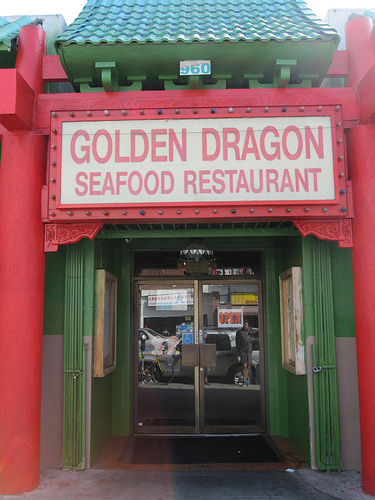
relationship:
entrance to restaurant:
[117, 245, 280, 444] [2, 0, 372, 497]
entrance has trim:
[117, 245, 280, 444] [114, 241, 282, 438]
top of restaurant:
[55, 0, 340, 82] [0, 0, 375, 500]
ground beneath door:
[19, 463, 370, 499] [133, 277, 267, 435]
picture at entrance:
[91, 269, 122, 378] [117, 245, 280, 444]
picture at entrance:
[274, 265, 308, 375] [117, 245, 280, 444]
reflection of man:
[230, 319, 257, 387] [230, 319, 258, 390]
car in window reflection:
[145, 327, 261, 384] [129, 281, 260, 388]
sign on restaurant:
[45, 106, 344, 213] [2, 0, 372, 497]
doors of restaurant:
[132, 277, 266, 436] [2, 0, 372, 497]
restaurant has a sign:
[2, 0, 372, 497] [45, 106, 344, 213]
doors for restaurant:
[132, 277, 266, 436] [2, 0, 372, 497]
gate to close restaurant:
[62, 245, 91, 473] [2, 0, 372, 497]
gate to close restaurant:
[299, 230, 348, 475] [2, 0, 372, 497]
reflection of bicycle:
[137, 338, 179, 385] [138, 348, 175, 385]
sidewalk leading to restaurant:
[13, 465, 370, 499] [2, 0, 372, 497]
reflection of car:
[143, 329, 264, 384] [145, 327, 261, 384]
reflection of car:
[140, 323, 181, 363] [138, 327, 183, 361]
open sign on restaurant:
[215, 307, 246, 328] [2, 0, 372, 497]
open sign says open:
[217, 308, 244, 328] [216, 308, 245, 328]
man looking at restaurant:
[230, 319, 258, 390] [2, 0, 372, 497]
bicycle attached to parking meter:
[139, 341, 177, 385] [136, 331, 148, 380]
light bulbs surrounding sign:
[38, 98, 351, 217] [45, 106, 344, 213]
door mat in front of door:
[130, 427, 276, 465] [133, 277, 267, 435]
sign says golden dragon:
[45, 106, 344, 213] [67, 120, 333, 166]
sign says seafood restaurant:
[45, 106, 344, 213] [74, 167, 323, 196]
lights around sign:
[41, 97, 349, 223] [45, 106, 344, 213]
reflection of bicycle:
[137, 338, 179, 385] [139, 341, 177, 385]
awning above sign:
[51, 0, 342, 80] [45, 106, 344, 213]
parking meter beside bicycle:
[136, 331, 148, 380] [139, 341, 177, 385]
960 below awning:
[176, 54, 214, 77] [51, 0, 342, 80]